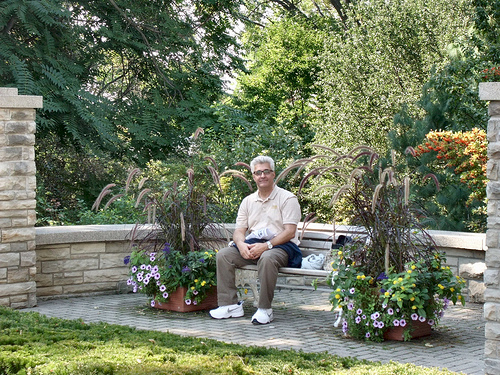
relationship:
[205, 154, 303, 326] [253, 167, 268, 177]
man wearing glasses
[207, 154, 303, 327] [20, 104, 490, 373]
man sitting in a garden